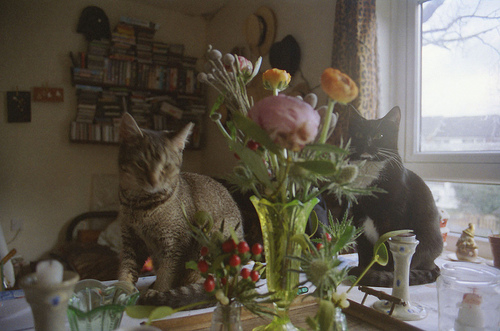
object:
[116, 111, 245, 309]
cat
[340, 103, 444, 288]
cat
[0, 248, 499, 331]
table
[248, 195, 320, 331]
vase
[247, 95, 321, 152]
flower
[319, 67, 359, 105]
flower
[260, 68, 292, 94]
flower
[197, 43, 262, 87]
flower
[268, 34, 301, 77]
hat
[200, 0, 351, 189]
wall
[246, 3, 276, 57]
hat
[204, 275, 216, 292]
berry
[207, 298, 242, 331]
vase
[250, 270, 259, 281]
berry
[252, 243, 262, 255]
berry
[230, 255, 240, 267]
berry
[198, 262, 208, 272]
berry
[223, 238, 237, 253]
berry